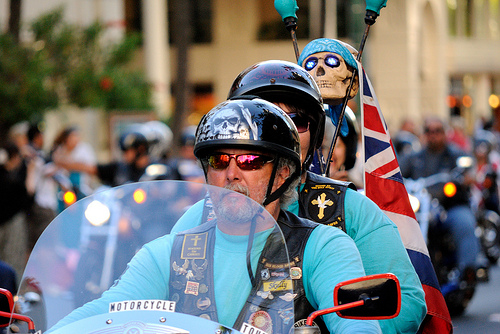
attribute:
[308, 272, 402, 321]
left side mirror — black, framed in red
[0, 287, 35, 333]
right side mirror — black, framed in red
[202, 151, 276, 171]
sunglasses — reflective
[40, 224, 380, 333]
shirt — blue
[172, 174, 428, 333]
shirt — blue, long sleeve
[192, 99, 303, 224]
helmet — black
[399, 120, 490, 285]
person — blurry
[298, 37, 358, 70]
bandana — blue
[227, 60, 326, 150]
helmet — black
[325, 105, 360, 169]
helmet — black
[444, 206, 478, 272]
pants — blue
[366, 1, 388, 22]
bulb — blue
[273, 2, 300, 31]
bulb — blue